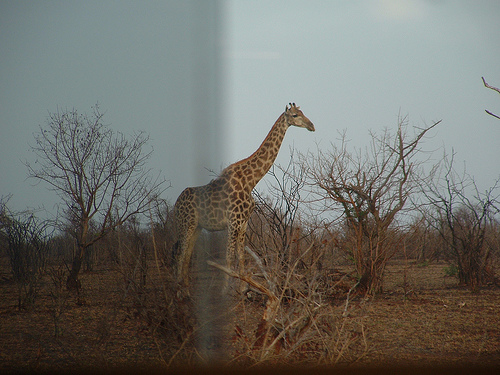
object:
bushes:
[320, 217, 402, 296]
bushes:
[2, 196, 55, 312]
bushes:
[201, 240, 363, 370]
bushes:
[111, 259, 201, 352]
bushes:
[421, 141, 500, 291]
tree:
[27, 100, 151, 295]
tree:
[306, 112, 440, 293]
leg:
[227, 227, 235, 282]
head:
[284, 102, 316, 132]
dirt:
[380, 309, 428, 336]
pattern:
[212, 180, 248, 216]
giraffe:
[165, 95, 318, 303]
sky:
[0, 0, 500, 133]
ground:
[26, 306, 496, 371]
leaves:
[34, 335, 63, 353]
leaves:
[89, 99, 101, 112]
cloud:
[0, 0, 500, 102]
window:
[0, 0, 199, 368]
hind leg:
[172, 222, 182, 288]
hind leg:
[190, 222, 201, 292]